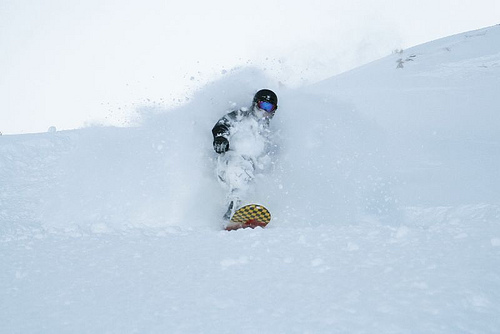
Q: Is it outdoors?
A: Yes, it is outdoors.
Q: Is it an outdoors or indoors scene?
A: It is outdoors.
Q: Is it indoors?
A: No, it is outdoors.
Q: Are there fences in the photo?
A: No, there are no fences.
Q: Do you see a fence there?
A: No, there are no fences.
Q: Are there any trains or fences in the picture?
A: No, there are no fences or trains.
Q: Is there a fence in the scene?
A: No, there are no fences.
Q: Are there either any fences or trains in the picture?
A: No, there are no fences or trains.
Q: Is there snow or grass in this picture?
A: Yes, there is snow.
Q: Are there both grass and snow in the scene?
A: No, there is snow but no grass.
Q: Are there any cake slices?
A: No, there are no cake slices.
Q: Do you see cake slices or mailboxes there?
A: No, there are no cake slices or mailboxes.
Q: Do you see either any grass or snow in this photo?
A: Yes, there is snow.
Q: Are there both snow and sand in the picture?
A: No, there is snow but no sand.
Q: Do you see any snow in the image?
A: Yes, there is snow.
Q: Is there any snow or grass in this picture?
A: Yes, there is snow.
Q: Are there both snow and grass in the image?
A: No, there is snow but no grass.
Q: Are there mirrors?
A: No, there are no mirrors.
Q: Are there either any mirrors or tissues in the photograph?
A: No, there are no mirrors or tissues.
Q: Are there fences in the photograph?
A: No, there are no fences.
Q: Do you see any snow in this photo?
A: Yes, there is snow.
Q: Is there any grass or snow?
A: Yes, there is snow.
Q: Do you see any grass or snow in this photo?
A: Yes, there is snow.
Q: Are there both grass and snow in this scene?
A: No, there is snow but no grass.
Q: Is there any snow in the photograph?
A: Yes, there is snow.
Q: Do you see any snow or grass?
A: Yes, there is snow.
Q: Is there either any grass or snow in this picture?
A: Yes, there is snow.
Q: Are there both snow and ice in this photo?
A: No, there is snow but no ice.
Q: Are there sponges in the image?
A: No, there are no sponges.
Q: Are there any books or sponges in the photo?
A: No, there are no sponges or books.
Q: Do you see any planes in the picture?
A: No, there are no planes.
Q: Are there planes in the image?
A: No, there are no planes.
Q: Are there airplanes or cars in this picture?
A: No, there are no airplanes or cars.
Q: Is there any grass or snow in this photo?
A: Yes, there is snow.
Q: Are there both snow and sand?
A: No, there is snow but no sand.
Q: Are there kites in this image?
A: No, there are no kites.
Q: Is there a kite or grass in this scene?
A: No, there are no kites or grass.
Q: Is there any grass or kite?
A: No, there are no kites or grass.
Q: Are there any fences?
A: No, there are no fences.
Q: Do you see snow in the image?
A: Yes, there is snow.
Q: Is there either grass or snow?
A: Yes, there is snow.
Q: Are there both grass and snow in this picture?
A: No, there is snow but no grass.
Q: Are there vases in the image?
A: No, there are no vases.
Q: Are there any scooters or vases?
A: No, there are no vases or scooters.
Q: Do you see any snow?
A: Yes, there is snow.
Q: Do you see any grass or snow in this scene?
A: Yes, there is snow.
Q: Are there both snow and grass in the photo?
A: No, there is snow but no grass.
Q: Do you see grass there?
A: No, there is no grass.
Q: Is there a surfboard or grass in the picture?
A: No, there are no grass or surfboards.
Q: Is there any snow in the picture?
A: Yes, there is snow.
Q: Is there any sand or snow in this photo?
A: Yes, there is snow.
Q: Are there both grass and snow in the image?
A: No, there is snow but no grass.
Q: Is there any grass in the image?
A: No, there is no grass.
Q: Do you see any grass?
A: No, there is no grass.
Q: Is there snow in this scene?
A: Yes, there is snow.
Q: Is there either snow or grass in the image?
A: Yes, there is snow.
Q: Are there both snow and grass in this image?
A: No, there is snow but no grass.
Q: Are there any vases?
A: No, there are no vases.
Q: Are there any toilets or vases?
A: No, there are no vases or toilets.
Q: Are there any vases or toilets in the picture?
A: No, there are no vases or toilets.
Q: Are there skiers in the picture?
A: No, there are no skiers.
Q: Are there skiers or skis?
A: No, there are no skiers or skis.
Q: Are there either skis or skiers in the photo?
A: No, there are no skiers or skis.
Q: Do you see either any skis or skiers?
A: No, there are no skiers or skis.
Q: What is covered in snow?
A: The mountain is covered in snow.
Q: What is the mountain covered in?
A: The mountain is covered in snow.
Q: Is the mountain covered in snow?
A: Yes, the mountain is covered in snow.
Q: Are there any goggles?
A: Yes, there are goggles.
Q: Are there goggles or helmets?
A: Yes, there are goggles.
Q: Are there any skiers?
A: No, there are no skiers.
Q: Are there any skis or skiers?
A: No, there are no skiers or skis.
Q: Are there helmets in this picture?
A: Yes, there is a helmet.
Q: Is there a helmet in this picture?
A: Yes, there is a helmet.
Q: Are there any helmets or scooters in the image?
A: Yes, there is a helmet.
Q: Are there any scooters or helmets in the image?
A: Yes, there is a helmet.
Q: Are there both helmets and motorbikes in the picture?
A: No, there is a helmet but no motorcycles.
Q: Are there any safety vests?
A: No, there are no safety vests.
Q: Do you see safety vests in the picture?
A: No, there are no safety vests.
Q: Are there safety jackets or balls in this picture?
A: No, there are no safety jackets or balls.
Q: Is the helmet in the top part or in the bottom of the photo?
A: The helmet is in the top of the image.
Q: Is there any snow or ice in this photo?
A: Yes, there is snow.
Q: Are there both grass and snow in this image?
A: No, there is snow but no grass.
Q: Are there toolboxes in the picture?
A: No, there are no toolboxes.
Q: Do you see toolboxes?
A: No, there are no toolboxes.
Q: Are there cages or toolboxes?
A: No, there are no toolboxes or cages.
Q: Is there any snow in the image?
A: Yes, there is snow.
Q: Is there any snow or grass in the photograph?
A: Yes, there is snow.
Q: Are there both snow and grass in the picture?
A: No, there is snow but no grass.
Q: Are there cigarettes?
A: No, there are no cigarettes.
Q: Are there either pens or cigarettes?
A: No, there are no cigarettes or pens.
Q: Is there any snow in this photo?
A: Yes, there is snow.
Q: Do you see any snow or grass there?
A: Yes, there is snow.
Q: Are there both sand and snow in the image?
A: No, there is snow but no sand.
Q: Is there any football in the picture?
A: No, there are no footballs.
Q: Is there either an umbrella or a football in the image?
A: No, there are no footballs or umbrellas.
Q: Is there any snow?
A: Yes, there is snow.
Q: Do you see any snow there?
A: Yes, there is snow.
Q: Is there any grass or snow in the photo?
A: Yes, there is snow.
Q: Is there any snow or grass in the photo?
A: Yes, there is snow.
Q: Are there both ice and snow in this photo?
A: No, there is snow but no ice.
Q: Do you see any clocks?
A: No, there are no clocks.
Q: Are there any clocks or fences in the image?
A: No, there are no clocks or fences.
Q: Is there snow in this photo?
A: Yes, there is snow.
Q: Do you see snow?
A: Yes, there is snow.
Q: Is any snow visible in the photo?
A: Yes, there is snow.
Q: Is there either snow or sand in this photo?
A: Yes, there is snow.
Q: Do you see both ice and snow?
A: No, there is snow but no ice.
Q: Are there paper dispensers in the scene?
A: No, there are no paper dispensers.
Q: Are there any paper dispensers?
A: No, there are no paper dispensers.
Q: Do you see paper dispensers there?
A: No, there are no paper dispensers.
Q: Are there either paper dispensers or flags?
A: No, there are no paper dispensers or flags.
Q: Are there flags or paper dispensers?
A: No, there are no paper dispensers or flags.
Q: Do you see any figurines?
A: No, there are no figurines.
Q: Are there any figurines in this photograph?
A: No, there are no figurines.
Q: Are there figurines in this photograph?
A: No, there are no figurines.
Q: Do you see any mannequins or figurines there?
A: No, there are no figurines or mannequins.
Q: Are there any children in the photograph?
A: No, there are no children.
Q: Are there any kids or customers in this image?
A: No, there are no kids or customers.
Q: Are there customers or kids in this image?
A: No, there are no kids or customers.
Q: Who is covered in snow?
A: The man is covered in snow.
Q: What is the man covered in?
A: The man is covered in snow.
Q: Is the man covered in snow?
A: Yes, the man is covered in snow.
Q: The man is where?
A: The man is on the hill.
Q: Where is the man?
A: The man is on the hill.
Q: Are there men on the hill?
A: Yes, there is a man on the hill.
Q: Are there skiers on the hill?
A: No, there is a man on the hill.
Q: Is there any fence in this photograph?
A: No, there are no fences.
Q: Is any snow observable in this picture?
A: Yes, there is snow.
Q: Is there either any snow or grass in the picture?
A: Yes, there is snow.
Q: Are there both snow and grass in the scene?
A: No, there is snow but no grass.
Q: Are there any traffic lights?
A: No, there are no traffic lights.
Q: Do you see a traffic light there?
A: No, there are no traffic lights.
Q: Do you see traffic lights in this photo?
A: No, there are no traffic lights.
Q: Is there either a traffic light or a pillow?
A: No, there are no traffic lights or pillows.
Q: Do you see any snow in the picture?
A: Yes, there is snow.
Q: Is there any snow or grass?
A: Yes, there is snow.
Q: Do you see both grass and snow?
A: No, there is snow but no grass.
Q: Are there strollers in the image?
A: No, there are no strollers.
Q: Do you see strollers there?
A: No, there are no strollers.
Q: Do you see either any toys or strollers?
A: No, there are no strollers or toys.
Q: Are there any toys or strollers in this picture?
A: No, there are no strollers or toys.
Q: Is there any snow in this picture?
A: Yes, there is snow.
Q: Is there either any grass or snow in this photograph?
A: Yes, there is snow.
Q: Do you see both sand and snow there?
A: No, there is snow but no sand.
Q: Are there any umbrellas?
A: No, there are no umbrellas.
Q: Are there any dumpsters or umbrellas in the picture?
A: No, there are no umbrellas or dumpsters.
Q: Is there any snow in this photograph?
A: Yes, there is snow.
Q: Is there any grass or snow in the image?
A: Yes, there is snow.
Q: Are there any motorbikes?
A: No, there are no motorbikes.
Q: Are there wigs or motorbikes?
A: No, there are no motorbikes or wigs.